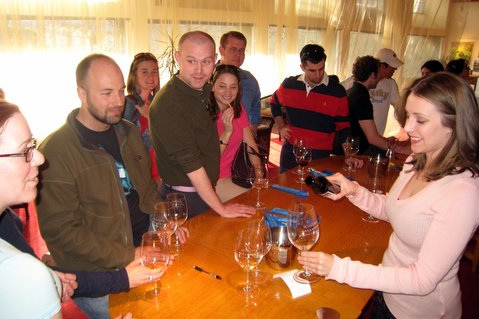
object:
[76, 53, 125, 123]
head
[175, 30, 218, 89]
head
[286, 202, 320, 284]
glass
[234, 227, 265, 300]
glass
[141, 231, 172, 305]
glass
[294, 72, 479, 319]
lady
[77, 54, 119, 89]
hair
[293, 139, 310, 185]
glass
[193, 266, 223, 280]
pen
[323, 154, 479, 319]
blouse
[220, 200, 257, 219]
hand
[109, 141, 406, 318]
table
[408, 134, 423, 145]
mouth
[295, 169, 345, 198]
bottle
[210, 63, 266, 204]
girl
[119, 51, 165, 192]
girl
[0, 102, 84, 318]
person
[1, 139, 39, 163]
glasses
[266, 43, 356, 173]
man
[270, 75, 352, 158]
shirt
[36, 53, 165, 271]
man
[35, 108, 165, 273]
jacket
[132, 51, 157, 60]
sunglasses